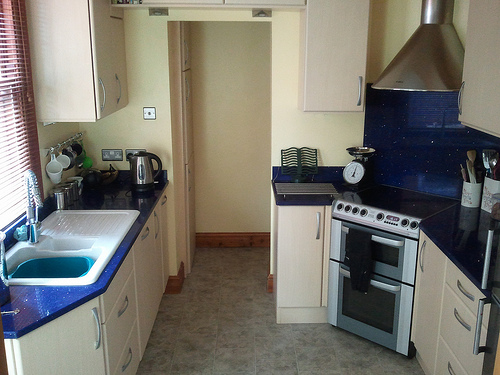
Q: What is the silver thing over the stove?
A: Vent hood.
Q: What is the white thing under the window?
A: Sink.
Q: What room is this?
A: Kitchen.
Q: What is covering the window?
A: Blinds.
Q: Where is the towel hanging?
A: Oven handle.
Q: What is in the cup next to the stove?
A: Wooden spoons.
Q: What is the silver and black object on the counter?
A: Coffee pot.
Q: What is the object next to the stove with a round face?
A: Scale.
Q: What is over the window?
A: Blinds.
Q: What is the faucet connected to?
A: Sink.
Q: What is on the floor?
A: Tile.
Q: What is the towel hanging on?
A: Stove.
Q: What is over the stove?
A: Vent.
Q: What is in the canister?
A: Silverware.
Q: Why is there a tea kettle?
A: To heat water.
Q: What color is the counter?
A: Blue.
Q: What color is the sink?
A: White.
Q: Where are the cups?
A: Hanging on the wall.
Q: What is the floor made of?
A: Linoleum.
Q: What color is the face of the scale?
A: White.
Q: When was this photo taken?
A: During the day.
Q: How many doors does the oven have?
A: Two.